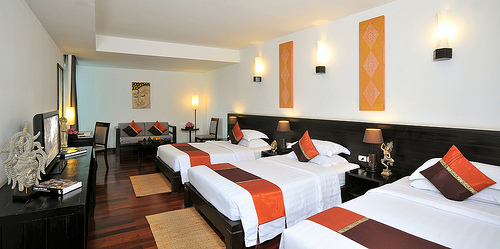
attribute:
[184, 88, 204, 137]
lamp — tall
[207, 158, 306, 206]
bed — queen size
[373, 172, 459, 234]
bed — queen size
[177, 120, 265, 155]
bed — queen size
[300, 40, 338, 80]
light — hanging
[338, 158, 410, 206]
table — small, black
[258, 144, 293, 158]
table — black, small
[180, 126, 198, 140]
table — small, black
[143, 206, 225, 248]
carpet — brown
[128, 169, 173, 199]
carpet — brown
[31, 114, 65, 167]
tv — flat screen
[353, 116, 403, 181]
lamp — brown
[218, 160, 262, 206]
bed spread — brown, Orange 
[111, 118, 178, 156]
sofa — gray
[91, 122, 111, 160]
chair — brown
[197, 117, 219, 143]
chair — brown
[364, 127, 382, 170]
lamp — small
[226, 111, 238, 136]
lamp — small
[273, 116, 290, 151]
lamp — small